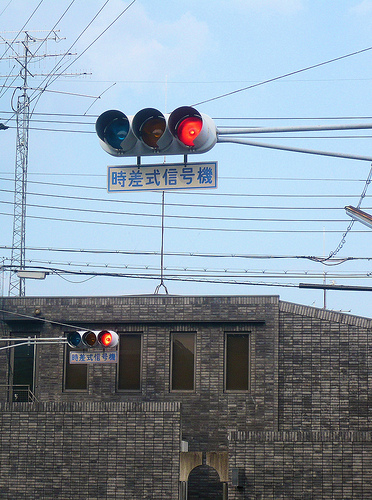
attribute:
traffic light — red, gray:
[77, 106, 239, 170]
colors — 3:
[104, 117, 196, 135]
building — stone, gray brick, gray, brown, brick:
[295, 333, 352, 373]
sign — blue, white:
[93, 160, 247, 200]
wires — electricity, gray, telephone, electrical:
[4, 21, 151, 91]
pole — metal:
[213, 125, 369, 146]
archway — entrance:
[165, 432, 248, 495]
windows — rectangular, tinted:
[51, 374, 276, 410]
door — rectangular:
[13, 335, 45, 406]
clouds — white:
[139, 26, 229, 58]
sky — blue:
[292, 18, 308, 19]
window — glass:
[222, 334, 254, 394]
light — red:
[170, 113, 203, 137]